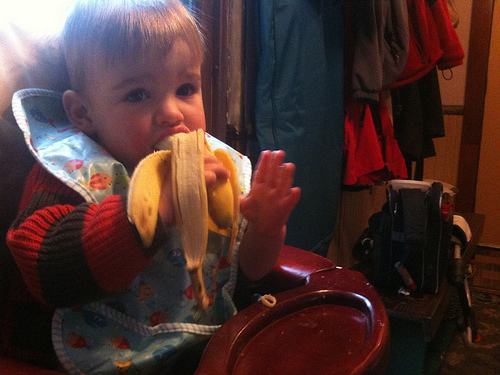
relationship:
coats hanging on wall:
[241, 0, 456, 245] [195, 1, 496, 257]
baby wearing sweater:
[5, 0, 300, 374] [7, 154, 277, 372]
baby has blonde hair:
[5, 0, 300, 374] [58, 0, 209, 93]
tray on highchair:
[202, 284, 387, 372] [3, 11, 392, 373]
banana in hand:
[150, 120, 237, 270] [150, 157, 230, 223]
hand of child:
[150, 157, 230, 223] [55, 45, 282, 322]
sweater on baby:
[45, 145, 97, 234] [5, 0, 300, 374]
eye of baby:
[176, 81, 198, 97] [5, 0, 300, 374]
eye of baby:
[121, 86, 155, 103] [5, 0, 300, 374]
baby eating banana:
[5, 0, 300, 374] [123, 128, 240, 307]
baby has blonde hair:
[5, 0, 300, 374] [58, 0, 209, 98]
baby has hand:
[5, 0, 300, 374] [230, 145, 313, 228]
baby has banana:
[5, 0, 300, 374] [123, 128, 240, 307]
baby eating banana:
[5, 0, 300, 374] [125, 120, 247, 307]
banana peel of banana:
[126, 127, 242, 311] [123, 128, 240, 307]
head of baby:
[56, 6, 287, 220] [5, 0, 300, 374]